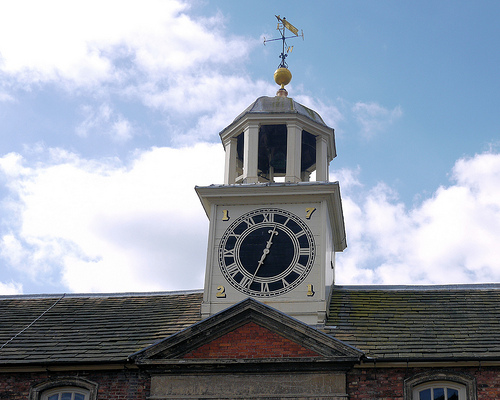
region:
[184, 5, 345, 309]
a clock tower on a roof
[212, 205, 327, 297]
a clock on a clock tower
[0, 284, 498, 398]
the top of an old building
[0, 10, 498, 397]
an old bank with a clock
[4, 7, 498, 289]
a clear sunny blue sky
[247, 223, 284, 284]
clock hands on a clock tower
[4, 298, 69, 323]
Section of a roof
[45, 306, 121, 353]
Section of a roof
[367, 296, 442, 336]
Section of a roof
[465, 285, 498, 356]
Section of a roof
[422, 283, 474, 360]
Section of a roof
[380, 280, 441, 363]
Section of a roof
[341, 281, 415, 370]
Section of a roof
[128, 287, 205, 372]
Section of a roof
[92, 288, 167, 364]
Section of a roof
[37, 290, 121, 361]
Section of a roof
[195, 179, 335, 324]
A clock is on the building.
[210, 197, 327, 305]
Numbers are on the face of the clock.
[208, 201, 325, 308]
The clock is black and white.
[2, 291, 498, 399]
The building is made of brick.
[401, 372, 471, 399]
The windows are on front of the building.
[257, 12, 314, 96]
There is a compass on top of the clock.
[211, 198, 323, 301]
The clock has Roman numerals.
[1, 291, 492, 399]
The building is brown brick.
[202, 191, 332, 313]
The numbers, 1, 2, and 7 are around the clock.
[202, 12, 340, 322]
The topper on the building is white.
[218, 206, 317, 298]
Round black clock face with white numbers, hands, and trim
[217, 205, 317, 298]
Clock with Roman numerals on face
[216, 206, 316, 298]
Four golden Arabic numbers in corners outside of clock face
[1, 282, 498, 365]
Long, shallow-pitched roof with worn, uneven shingles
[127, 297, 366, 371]
Decorative roof gable below clock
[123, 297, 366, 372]
Roof gable fronted with red brick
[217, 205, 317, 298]
Clock showing time of 12:24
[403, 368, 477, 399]
Arched top of window in brick wall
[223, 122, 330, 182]
White columns supporting dome of cupola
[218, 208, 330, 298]
Blue and white clock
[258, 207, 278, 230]
White roman numeral on a clock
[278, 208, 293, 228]
White roman numeral on a clock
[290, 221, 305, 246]
White roman numeral on a clock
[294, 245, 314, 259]
White roman numeral on a clock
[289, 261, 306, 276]
White roman numeral on a clock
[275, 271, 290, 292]
White roman numeral on a clock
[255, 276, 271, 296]
White roman numeral on a clock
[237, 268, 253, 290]
White roman numeral on a clock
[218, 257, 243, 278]
White roman numeral on a clock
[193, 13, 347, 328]
White clock tower on top of brick building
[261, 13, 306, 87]
Weather vane on top of clock tower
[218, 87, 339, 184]
Open cupola on top of clock tower